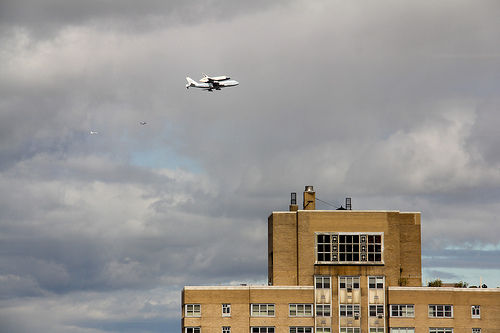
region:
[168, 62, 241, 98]
white airplane carrying space shuttle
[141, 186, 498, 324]
white and tan buidling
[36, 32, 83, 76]
white clouds in blue sky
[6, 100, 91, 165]
white clouds in blue sky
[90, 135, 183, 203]
white clouds in blue sky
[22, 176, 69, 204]
white clouds in blue sky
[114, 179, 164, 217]
white clouds in blue sky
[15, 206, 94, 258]
white clouds in blue sky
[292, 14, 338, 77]
white clouds in blue sky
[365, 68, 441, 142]
white clouds in blue sky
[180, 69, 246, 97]
a white airplane carrying another airplane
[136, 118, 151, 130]
an airplane in the sky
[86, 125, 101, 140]
a white airplane in the sky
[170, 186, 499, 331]
a large brown building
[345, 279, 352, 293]
a window a/c unit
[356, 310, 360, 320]
a window a/c unit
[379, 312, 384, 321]
a window a/c unit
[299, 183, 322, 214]
a chimney to a building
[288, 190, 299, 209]
a chimney to a building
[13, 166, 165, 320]
dark clouds in the sky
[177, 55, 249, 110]
white space shuttle on white airplane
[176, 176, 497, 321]
brown and white building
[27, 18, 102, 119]
white clouds in blue sky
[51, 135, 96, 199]
white clouds in blue sky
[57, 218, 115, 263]
white clouds in blue sky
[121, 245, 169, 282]
white clouds in blue sky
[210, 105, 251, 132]
white clouds in blue sky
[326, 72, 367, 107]
white clouds in blue sky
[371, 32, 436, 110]
white clouds in blue sky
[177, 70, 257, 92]
A white and black plane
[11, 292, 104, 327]
A white and cloud sky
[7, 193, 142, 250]
A white and cloud sky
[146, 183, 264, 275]
A white and cloud sky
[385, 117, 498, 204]
A white and cloud sky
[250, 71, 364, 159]
A dark cloud sky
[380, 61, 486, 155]
A dark cloud sky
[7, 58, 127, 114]
A dark cloud sky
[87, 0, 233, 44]
A dark cloud sky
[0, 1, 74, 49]
A dark cloud sky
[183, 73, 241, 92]
A plane is flying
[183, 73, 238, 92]
The space shuttle is on top of the plane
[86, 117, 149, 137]
There are two jets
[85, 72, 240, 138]
The jets follow behind the plane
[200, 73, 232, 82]
The space shuttle is black and white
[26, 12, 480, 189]
The sky is cloudy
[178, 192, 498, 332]
The building is brown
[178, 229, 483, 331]
The building has many windows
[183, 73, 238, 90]
The plane is carrying the space shuttle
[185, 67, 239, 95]
The plane is flying